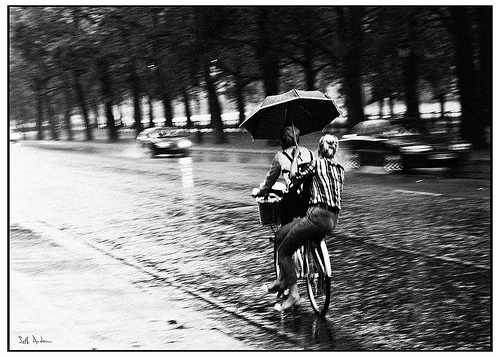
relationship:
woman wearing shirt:
[267, 131, 347, 309] [290, 153, 347, 215]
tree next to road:
[111, 4, 161, 156] [13, 122, 497, 356]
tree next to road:
[144, 6, 191, 147] [13, 122, 497, 356]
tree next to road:
[185, 0, 242, 142] [13, 122, 497, 356]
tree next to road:
[56, 24, 106, 139] [13, 122, 497, 356]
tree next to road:
[5, 0, 89, 142] [13, 122, 497, 356]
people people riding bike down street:
[252, 126, 344, 310] [111, 147, 234, 323]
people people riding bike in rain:
[252, 126, 344, 310] [147, 254, 454, 347]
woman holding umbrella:
[271, 125, 297, 150] [236, 93, 349, 136]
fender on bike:
[314, 236, 334, 281] [245, 178, 342, 320]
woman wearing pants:
[267, 134, 344, 310] [274, 199, 342, 282]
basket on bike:
[254, 185, 285, 228] [250, 178, 340, 312]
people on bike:
[250, 124, 344, 312] [250, 178, 340, 312]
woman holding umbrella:
[267, 134, 344, 310] [237, 86, 341, 161]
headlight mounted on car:
[152, 139, 172, 149] [132, 123, 192, 157]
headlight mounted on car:
[174, 139, 193, 149] [132, 123, 192, 157]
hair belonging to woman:
[315, 130, 339, 159] [260, 129, 347, 312]